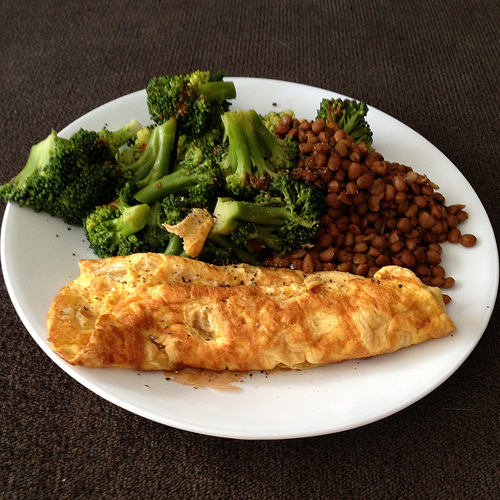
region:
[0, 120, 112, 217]
piece of broccoli on a white plate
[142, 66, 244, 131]
piece of broccoli on a white plate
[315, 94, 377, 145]
piece of broccoli on a white plate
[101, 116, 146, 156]
piece of broccoli on a white plate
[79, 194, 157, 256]
piece of broccoli on a white plate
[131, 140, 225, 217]
piece of broccoli on a white plate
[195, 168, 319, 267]
piece of broccoli on a white plate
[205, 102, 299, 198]
piece of broccoli on a white plate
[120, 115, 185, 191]
piece of broccoli on a white plate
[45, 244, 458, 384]
omelate on a white plate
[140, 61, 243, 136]
The broccoli is green.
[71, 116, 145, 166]
The broccoli is green.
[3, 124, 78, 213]
The broccoli is green.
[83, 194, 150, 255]
The broccoli is green.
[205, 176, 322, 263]
The broccoli is green.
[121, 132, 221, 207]
The broccoli is green.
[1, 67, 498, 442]
The plate is white.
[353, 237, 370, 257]
A piece of food.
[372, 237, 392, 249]
A piece of food.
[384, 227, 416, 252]
A piece of food.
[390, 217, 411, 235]
A piece of food.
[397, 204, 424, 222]
A piece of food.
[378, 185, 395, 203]
A piece of food.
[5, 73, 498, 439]
omelette is on plate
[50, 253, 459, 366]
omelette is color yellow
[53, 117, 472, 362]
omelette is near beans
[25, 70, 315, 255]
broccoli is color green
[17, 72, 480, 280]
broccolis are near beans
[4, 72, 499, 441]
broccolis are on the plate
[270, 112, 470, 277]
beans are color brown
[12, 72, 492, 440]
beans are on the plate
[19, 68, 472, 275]
beans are near broccolis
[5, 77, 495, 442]
plate is color white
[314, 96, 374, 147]
broccoli piece on the white plate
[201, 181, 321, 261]
broccoli piece on the white plate